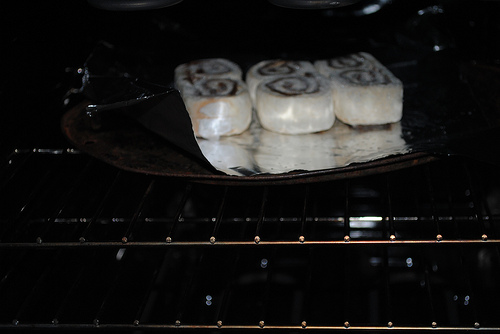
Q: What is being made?
A: Cinnamon rolls.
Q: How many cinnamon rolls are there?
A: 6.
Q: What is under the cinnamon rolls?
A: Aluminum foil.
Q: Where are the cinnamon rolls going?
A: Into the oven.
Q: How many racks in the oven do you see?
A: 2.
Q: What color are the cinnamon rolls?
A: Tan.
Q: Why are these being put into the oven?
A: To cook.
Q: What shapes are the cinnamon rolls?
A: Circles.